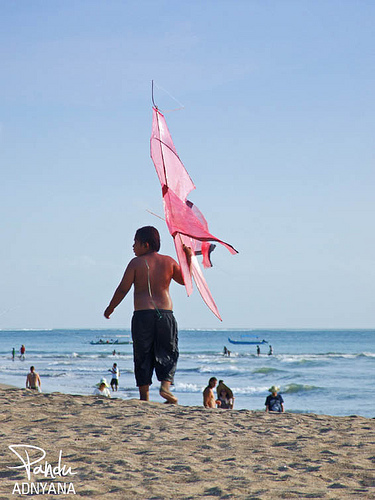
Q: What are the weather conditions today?
A: It is foggy.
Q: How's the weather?
A: It is foggy.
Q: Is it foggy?
A: Yes, it is foggy.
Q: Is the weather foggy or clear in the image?
A: It is foggy.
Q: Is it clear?
A: No, it is foggy.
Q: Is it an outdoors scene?
A: Yes, it is outdoors.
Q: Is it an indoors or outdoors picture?
A: It is outdoors.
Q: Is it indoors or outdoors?
A: It is outdoors.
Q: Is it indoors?
A: No, it is outdoors.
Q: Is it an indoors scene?
A: No, it is outdoors.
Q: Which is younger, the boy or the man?
A: The boy is younger than the man.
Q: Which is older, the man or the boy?
A: The man is older than the boy.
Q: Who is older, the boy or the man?
A: The man is older than the boy.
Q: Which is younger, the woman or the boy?
A: The boy is younger than the woman.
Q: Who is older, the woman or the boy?
A: The woman is older than the boy.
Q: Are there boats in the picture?
A: Yes, there is a boat.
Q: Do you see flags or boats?
A: Yes, there is a boat.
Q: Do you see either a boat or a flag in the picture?
A: Yes, there is a boat.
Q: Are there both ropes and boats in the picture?
A: No, there is a boat but no ropes.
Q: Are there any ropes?
A: No, there are no ropes.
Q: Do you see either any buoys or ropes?
A: No, there are no ropes or buoys.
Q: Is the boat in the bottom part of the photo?
A: Yes, the boat is in the bottom of the image.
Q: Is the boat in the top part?
A: No, the boat is in the bottom of the image.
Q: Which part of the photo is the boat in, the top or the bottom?
A: The boat is in the bottom of the image.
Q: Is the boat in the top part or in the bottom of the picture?
A: The boat is in the bottom of the image.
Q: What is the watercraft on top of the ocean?
A: The watercraft is a boat.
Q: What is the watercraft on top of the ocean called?
A: The watercraft is a boat.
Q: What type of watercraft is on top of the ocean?
A: The watercraft is a boat.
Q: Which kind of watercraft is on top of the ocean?
A: The watercraft is a boat.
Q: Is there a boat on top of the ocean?
A: Yes, there is a boat on top of the ocean.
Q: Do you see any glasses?
A: No, there are no glasses.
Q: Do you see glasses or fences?
A: No, there are no glasses or fences.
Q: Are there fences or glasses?
A: No, there are no glasses or fences.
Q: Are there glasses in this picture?
A: No, there are no glasses.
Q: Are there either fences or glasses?
A: No, there are no glasses or fences.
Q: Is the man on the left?
A: Yes, the man is on the left of the image.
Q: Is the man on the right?
A: No, the man is on the left of the image.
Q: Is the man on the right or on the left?
A: The man is on the left of the image.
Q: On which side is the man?
A: The man is on the left of the image.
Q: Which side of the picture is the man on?
A: The man is on the left of the image.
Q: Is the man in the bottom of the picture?
A: Yes, the man is in the bottom of the image.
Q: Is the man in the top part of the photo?
A: No, the man is in the bottom of the image.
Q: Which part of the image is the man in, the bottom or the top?
A: The man is in the bottom of the image.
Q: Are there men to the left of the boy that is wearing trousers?
A: Yes, there is a man to the left of the boy.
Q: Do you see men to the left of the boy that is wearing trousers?
A: Yes, there is a man to the left of the boy.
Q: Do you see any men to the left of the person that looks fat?
A: Yes, there is a man to the left of the boy.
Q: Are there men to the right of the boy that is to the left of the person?
A: No, the man is to the left of the boy.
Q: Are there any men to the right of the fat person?
A: No, the man is to the left of the boy.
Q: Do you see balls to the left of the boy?
A: No, there is a man to the left of the boy.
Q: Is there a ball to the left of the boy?
A: No, there is a man to the left of the boy.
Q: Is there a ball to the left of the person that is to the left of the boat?
A: No, there is a man to the left of the boy.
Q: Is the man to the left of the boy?
A: Yes, the man is to the left of the boy.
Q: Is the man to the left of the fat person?
A: Yes, the man is to the left of the boy.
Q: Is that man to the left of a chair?
A: No, the man is to the left of the boy.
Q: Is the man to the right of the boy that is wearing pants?
A: No, the man is to the left of the boy.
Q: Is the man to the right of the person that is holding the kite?
A: No, the man is to the left of the boy.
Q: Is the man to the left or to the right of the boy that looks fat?
A: The man is to the left of the boy.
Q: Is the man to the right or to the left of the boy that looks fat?
A: The man is to the left of the boy.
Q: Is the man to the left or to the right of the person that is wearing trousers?
A: The man is to the left of the boy.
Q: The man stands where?
A: The man stands on the beach.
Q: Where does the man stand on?
A: The man stands on the beach.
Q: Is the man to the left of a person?
A: Yes, the man is to the left of a person.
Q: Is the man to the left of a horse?
A: No, the man is to the left of a person.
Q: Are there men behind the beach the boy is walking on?
A: Yes, there is a man behind the beach.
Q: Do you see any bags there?
A: No, there are no bags.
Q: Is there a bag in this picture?
A: No, there are no bags.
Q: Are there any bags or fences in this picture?
A: No, there are no bags or fences.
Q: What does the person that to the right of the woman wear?
A: The person wears a shirt.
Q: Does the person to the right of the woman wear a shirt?
A: Yes, the person wears a shirt.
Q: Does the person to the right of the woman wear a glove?
A: No, the person wears a shirt.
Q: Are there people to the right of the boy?
A: Yes, there is a person to the right of the boy.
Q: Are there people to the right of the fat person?
A: Yes, there is a person to the right of the boy.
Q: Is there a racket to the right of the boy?
A: No, there is a person to the right of the boy.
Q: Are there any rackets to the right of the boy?
A: No, there is a person to the right of the boy.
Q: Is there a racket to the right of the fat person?
A: No, there is a person to the right of the boy.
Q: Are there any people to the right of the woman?
A: Yes, there is a person to the right of the woman.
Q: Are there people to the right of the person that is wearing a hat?
A: Yes, there is a person to the right of the woman.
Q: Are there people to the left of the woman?
A: No, the person is to the right of the woman.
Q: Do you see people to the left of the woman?
A: No, the person is to the right of the woman.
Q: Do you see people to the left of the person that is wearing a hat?
A: No, the person is to the right of the woman.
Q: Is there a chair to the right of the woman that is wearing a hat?
A: No, there is a person to the right of the woman.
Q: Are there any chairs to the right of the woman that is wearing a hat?
A: No, there is a person to the right of the woman.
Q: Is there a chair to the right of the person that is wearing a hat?
A: No, there is a person to the right of the woman.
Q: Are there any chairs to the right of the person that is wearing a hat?
A: No, there is a person to the right of the woman.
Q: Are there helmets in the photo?
A: No, there are no helmets.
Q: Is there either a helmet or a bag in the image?
A: No, there are no helmets or bags.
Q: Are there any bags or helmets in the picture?
A: No, there are no helmets or bags.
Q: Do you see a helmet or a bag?
A: No, there are no helmets or bags.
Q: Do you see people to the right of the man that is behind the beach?
A: Yes, there is a person to the right of the man.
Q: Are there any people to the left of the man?
A: No, the person is to the right of the man.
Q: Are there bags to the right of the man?
A: No, there is a person to the right of the man.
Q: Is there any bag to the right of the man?
A: No, there is a person to the right of the man.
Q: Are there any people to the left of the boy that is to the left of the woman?
A: Yes, there is a person to the left of the boy.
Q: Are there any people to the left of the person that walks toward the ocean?
A: Yes, there is a person to the left of the boy.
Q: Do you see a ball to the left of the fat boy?
A: No, there is a person to the left of the boy.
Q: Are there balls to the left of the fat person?
A: No, there is a person to the left of the boy.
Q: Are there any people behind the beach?
A: Yes, there is a person behind the beach.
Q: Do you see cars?
A: No, there are no cars.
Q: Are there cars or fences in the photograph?
A: No, there are no cars or fences.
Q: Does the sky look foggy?
A: Yes, the sky is foggy.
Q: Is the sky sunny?
A: No, the sky is foggy.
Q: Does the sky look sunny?
A: No, the sky is foggy.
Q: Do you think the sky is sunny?
A: No, the sky is foggy.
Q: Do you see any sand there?
A: Yes, there is sand.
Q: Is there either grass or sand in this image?
A: Yes, there is sand.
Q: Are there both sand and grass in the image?
A: No, there is sand but no grass.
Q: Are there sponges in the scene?
A: No, there are no sponges.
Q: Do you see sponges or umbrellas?
A: No, there are no sponges or umbrellas.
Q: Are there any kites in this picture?
A: Yes, there is a kite.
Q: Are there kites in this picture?
A: Yes, there is a kite.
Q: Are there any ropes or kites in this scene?
A: Yes, there is a kite.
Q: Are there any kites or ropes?
A: Yes, there is a kite.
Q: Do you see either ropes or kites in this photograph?
A: Yes, there is a kite.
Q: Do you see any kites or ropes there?
A: Yes, there is a kite.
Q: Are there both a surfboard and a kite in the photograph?
A: No, there is a kite but no surfboards.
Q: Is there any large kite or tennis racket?
A: Yes, there is a large kite.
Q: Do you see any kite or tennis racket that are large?
A: Yes, the kite is large.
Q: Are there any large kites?
A: Yes, there is a large kite.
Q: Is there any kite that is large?
A: Yes, there is a kite that is large.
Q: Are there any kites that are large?
A: Yes, there is a kite that is large.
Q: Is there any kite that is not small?
A: Yes, there is a large kite.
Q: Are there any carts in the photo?
A: No, there are no carts.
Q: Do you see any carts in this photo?
A: No, there are no carts.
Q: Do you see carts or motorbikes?
A: No, there are no carts or motorbikes.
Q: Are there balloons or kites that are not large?
A: No, there is a kite but it is large.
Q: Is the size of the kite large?
A: Yes, the kite is large.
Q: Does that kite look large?
A: Yes, the kite is large.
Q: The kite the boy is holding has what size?
A: The kite is large.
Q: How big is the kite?
A: The kite is large.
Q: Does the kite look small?
A: No, the kite is large.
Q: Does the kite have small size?
A: No, the kite is large.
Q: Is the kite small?
A: No, the kite is large.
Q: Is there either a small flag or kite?
A: No, there is a kite but it is large.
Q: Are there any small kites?
A: No, there is a kite but it is large.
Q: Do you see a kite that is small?
A: No, there is a kite but it is large.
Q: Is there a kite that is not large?
A: No, there is a kite but it is large.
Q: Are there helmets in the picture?
A: No, there are no helmets.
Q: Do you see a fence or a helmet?
A: No, there are no helmets or fences.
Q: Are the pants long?
A: Yes, the pants are long.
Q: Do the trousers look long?
A: Yes, the trousers are long.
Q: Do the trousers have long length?
A: Yes, the trousers are long.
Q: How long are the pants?
A: The pants are long.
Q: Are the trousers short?
A: No, the trousers are long.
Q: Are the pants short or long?
A: The pants are long.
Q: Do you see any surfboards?
A: No, there are no surfboards.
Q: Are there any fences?
A: No, there are no fences.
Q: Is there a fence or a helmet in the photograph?
A: No, there are no fences or helmets.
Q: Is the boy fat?
A: Yes, the boy is fat.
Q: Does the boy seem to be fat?
A: Yes, the boy is fat.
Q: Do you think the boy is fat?
A: Yes, the boy is fat.